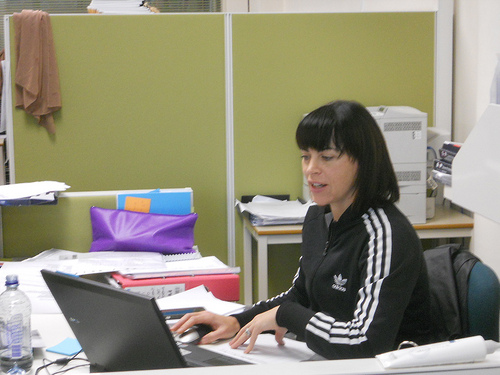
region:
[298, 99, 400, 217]
Woman has dark hair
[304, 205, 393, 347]
White stripes on a black jacket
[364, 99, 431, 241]
Hand on a computer mouse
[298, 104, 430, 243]
Printer on a table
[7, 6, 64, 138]
Sweater hanging from a wall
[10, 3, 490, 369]
Woman working in an office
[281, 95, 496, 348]
Woman sitting in a chair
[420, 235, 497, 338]
Black coat hanging over a chair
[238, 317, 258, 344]
Ring around a finger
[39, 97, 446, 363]
Woman looking at laptop computer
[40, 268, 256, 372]
a black laptop on top of the desk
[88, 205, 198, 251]
a purple office supply bag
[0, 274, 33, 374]
a bottle of water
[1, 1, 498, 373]
a woman in a cubicle office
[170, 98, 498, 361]
a woman sitting in a green chair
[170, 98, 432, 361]
a woman in a black and white Adidas sweat jacket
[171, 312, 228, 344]
a black and silver computer mouse under the woman's hand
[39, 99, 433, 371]
a woman with black hair sitting at a desk using the laptop computer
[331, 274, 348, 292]
Adidas logo on the front of the sweat jacket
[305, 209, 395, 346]
white stripes on the sleeve of the sweat jacket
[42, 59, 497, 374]
A woman working in a cubicle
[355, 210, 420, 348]
White stripes on the woman's jacket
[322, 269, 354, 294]
An adidas logo on the woman's jacket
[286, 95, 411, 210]
The woman has shoulder length hair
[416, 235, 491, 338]
A black sweater on the chair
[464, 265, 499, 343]
A blue computer chair by the desk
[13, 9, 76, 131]
An orange shirt hanging over the cubicle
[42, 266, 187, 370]
A black laptop on the desk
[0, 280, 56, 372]
A clear water bottle by the laptop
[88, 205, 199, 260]
A purple bag by the binder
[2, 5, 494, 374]
A woman in an office.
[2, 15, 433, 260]
The cubicle wall is green.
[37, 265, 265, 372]
The laptop is black.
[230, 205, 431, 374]
The woman is wearing a black track suit jacket with white stripes.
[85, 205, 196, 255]
A small purple bag.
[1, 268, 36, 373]
A bottle of water.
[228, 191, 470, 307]
A table next to the cubicle wall.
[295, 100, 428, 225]
A printer is on top of the table.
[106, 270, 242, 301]
The binder is pink.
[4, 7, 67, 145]
An article of clothing handing over the cubicle wall.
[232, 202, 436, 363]
a black jacket with white stripes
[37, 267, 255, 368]
a black laptop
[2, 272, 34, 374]
a clear plastic water bottle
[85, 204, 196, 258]
a purple bag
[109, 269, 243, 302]
a red binder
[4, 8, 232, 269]
an office cubicle divider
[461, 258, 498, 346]
a blue desk chair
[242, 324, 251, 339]
a ring on a finger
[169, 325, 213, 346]
a mouse in a hand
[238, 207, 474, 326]
a table behind a woman